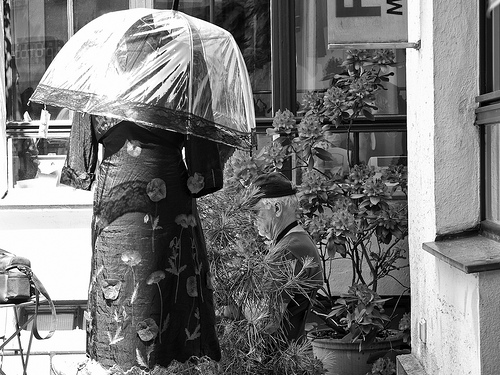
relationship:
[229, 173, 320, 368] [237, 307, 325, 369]
man sitting on step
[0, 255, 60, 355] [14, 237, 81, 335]
bag sitting on table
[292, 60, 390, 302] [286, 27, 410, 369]
flowers on plant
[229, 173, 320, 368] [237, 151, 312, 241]
man wearing hat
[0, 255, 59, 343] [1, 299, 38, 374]
bag sitting on table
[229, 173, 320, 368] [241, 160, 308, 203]
man wearing hat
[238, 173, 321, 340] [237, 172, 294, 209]
man wearing cap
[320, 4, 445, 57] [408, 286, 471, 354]
sign on wall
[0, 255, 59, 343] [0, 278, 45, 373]
bag on table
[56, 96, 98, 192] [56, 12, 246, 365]
sleeve on floral dress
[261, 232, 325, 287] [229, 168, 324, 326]
shirt on man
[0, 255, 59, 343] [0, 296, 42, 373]
bag on table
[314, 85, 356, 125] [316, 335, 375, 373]
flower in large pot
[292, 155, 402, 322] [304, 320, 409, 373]
plant in pot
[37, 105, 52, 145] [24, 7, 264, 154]
tag on canopy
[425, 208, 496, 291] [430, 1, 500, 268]
ledge on window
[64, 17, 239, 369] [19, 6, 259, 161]
person holding umbrella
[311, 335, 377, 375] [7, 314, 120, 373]
large pot on ground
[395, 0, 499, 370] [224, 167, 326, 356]
building near person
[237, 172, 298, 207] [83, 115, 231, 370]
cap on person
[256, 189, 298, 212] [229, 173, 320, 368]
hair on man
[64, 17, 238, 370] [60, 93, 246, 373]
person wearing dress